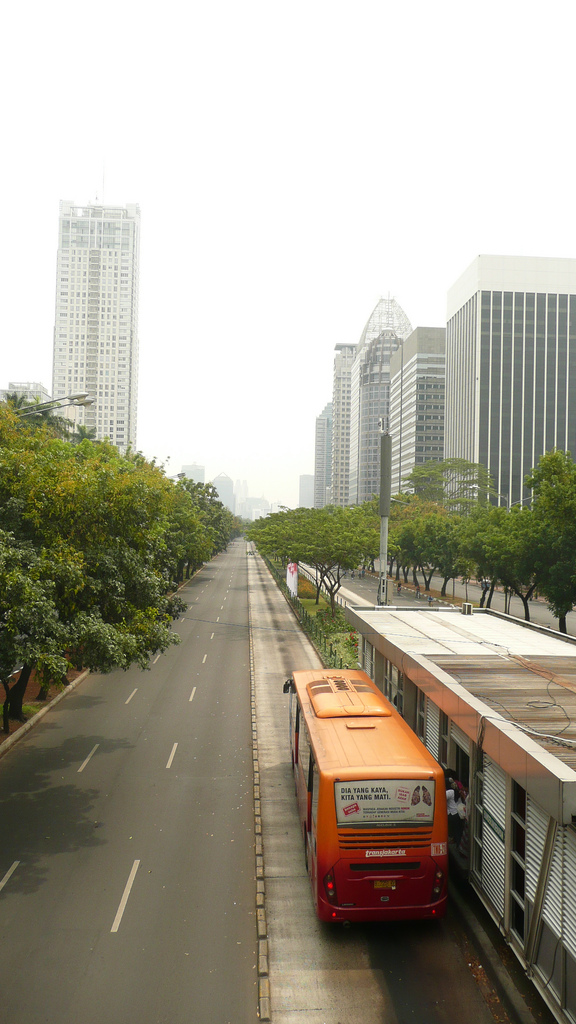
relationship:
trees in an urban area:
[257, 499, 386, 581] [54, 190, 546, 659]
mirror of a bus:
[276, 675, 289, 690] [278, 661, 454, 919]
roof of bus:
[292, 665, 439, 779] [278, 661, 454, 919]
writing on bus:
[361, 842, 413, 858] [278, 661, 454, 919]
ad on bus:
[331, 779, 435, 830] [278, 661, 454, 919]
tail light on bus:
[320, 872, 340, 893] [259, 633, 464, 951]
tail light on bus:
[423, 906, 443, 917] [259, 633, 464, 951]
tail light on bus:
[323, 910, 345, 921] [283, 663, 461, 952]